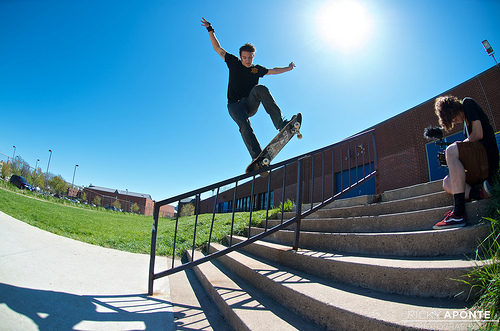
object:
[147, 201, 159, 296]
bar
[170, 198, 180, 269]
bar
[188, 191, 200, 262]
bar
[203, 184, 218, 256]
bar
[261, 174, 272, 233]
bar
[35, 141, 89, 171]
lights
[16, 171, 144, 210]
lot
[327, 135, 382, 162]
sign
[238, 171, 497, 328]
staircase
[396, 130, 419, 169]
wall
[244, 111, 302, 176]
skate board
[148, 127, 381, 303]
rail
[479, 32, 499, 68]
lamp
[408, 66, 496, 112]
roof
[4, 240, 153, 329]
ground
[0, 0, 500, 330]
scene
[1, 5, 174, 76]
blue sky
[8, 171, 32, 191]
vehicle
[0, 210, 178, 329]
sidewalk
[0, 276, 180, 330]
shadow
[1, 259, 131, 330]
sidewalk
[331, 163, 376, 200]
window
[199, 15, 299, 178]
guy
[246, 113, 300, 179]
feet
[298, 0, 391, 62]
sun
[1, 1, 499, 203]
sky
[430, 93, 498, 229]
boy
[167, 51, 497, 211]
building